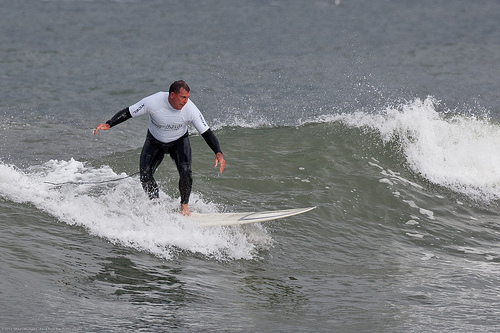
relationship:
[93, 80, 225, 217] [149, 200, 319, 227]
man on surfboard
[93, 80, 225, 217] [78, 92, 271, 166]
man extending arm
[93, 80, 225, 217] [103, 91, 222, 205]
man wearing wetsuit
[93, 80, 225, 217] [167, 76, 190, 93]
man has hair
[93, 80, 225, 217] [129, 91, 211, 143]
man has shirt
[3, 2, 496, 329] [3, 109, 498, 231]
water causing wave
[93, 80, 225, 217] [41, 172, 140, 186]
man has black lead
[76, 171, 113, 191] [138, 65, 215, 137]
surfboard leash attached to man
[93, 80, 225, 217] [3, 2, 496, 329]
man on water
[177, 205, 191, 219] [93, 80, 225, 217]
foot on man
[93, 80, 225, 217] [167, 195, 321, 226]
man on surfboard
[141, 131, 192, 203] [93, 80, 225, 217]
pants on man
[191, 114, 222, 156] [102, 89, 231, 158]
sleeve on shirt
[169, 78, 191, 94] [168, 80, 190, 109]
hair on head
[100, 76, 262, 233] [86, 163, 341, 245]
man on surfboard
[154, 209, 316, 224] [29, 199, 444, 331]
surfboard on water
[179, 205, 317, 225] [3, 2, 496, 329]
surfboard on water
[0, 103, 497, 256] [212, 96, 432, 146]
wave has crest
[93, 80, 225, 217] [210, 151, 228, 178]
man has hand